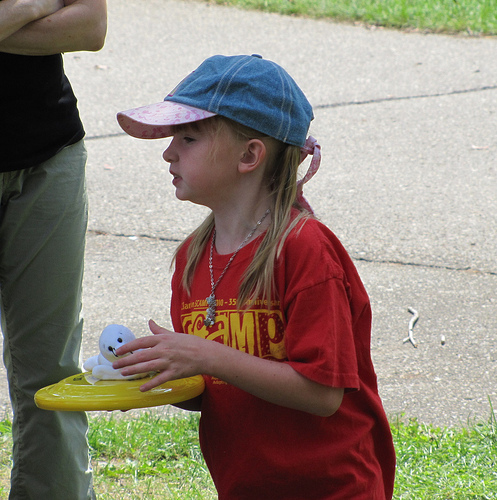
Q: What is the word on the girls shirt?
A: Camp.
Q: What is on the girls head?
A: A baseball cap.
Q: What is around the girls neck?
A: A necklace.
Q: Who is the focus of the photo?
A: The little girl.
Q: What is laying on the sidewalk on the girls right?
A: A stick.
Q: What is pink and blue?
A: The girls hat.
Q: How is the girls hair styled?
A: Down.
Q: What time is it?
A: Afternoon.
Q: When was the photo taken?
A: During the daytime.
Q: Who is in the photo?
A: A girl.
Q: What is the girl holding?
A: Frisbee.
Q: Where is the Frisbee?
A: In girl's hand.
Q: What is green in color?
A: Grass.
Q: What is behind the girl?
A: Sidewalk.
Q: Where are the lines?
A: On the cement.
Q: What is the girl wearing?
A: A hat.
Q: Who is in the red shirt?
A: A girl.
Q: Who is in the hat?
A: A girl.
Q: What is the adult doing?
A: Standing.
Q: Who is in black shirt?
A: A adult.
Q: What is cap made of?
A: Jean.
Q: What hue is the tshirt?
A: Red.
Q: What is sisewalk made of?
A: Cement.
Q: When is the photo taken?
A: Daytime.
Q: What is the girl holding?
A: Frisbee.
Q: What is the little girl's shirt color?
A: Red.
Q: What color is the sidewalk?
A: Grey.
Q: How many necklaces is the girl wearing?
A: One.